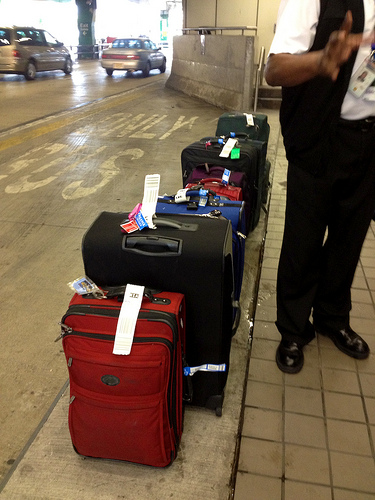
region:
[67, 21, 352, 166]
picture taken outdoors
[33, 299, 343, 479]
picture taken during the day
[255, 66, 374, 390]
a man is standing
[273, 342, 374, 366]
the man is wearing black shoes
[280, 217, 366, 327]
the man is wearing black pants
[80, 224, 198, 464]
many pieces of luggage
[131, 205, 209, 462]
the luggage is on the sidewalk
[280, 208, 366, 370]
The man is an airport porter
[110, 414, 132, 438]
The luggage is red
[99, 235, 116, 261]
the luggage is black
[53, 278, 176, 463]
suitcase on the sidewalk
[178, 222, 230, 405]
suitcase on the sidewalk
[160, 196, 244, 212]
suitcase on the sidewalk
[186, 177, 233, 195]
suitcase on the sidewalk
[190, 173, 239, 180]
suitcase on the sidewalk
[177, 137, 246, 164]
suitcase on the sidewalk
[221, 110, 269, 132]
suitcase on the sidewalk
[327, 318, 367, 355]
black shoe on person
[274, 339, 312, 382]
black shoe on person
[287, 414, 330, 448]
square tile on floor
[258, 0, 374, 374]
Person in the foreground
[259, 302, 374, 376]
Person is wearing black shoes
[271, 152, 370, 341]
Person is wearing black pants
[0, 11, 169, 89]
Cars are in the background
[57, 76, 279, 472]
A line of traveling bags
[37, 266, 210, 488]
Traveling bag in the foreground is red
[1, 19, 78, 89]
A van in the background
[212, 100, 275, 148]
Bag in the background is dark green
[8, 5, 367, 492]
Photo was taken in the daytime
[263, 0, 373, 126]
Person is wearing a white shirt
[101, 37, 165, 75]
a car driving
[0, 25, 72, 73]
a car driving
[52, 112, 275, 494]
a row of luggage on the sidewalk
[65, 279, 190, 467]
a red luggage on a sidewalk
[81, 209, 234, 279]
a black luggage on a sidewalk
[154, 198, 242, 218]
a blue luggage on a sidewalk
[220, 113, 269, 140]
a green luggage on a sidewalk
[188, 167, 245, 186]
a purple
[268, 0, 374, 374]
a person standing next to a row of luggage on a sidewalk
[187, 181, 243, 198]
a red luggage on a sidewalk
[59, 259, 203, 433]
A red suitcase on the ground.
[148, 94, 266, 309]
Suitcases on the ground.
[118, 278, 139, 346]
A white tag on the red suitcase.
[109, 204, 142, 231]
A red tag on the black suitcase.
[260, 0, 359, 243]
A man standing near the luggage.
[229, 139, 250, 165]
A green tag on the black suitcase.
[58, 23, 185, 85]
Cars in the airport terminal.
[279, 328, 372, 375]
The person is wearing black shoes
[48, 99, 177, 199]
The street has white letters on it.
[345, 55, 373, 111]
The person is wearing a work badge.